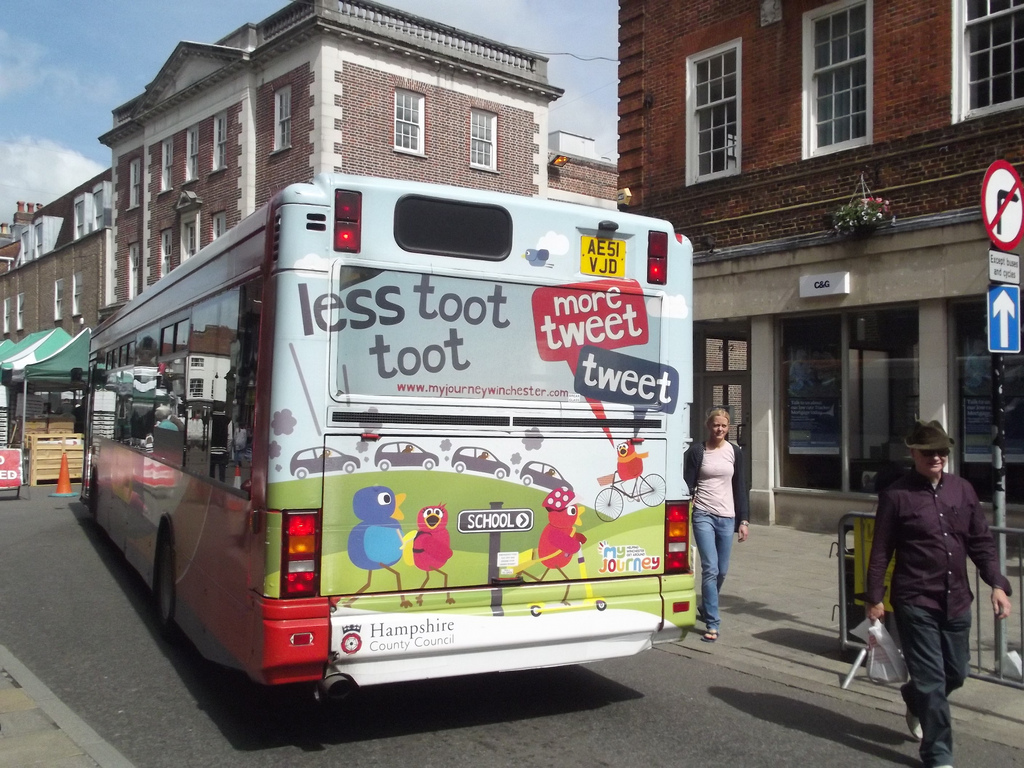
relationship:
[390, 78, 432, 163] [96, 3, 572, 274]
window on a building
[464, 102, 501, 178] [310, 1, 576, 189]
window on a building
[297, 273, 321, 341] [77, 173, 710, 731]
letter on bus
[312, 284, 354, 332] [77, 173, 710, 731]
letter on bus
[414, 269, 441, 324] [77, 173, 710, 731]
letter on bus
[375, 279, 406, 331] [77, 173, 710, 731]
letter on bus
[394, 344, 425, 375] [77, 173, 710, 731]
letter on bus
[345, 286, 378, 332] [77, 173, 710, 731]
letter on bus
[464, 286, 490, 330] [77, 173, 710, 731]
letter on bus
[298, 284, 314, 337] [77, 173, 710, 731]
letter on bus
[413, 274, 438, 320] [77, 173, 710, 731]
letter on bus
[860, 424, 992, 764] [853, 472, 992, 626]
man wearing shirt